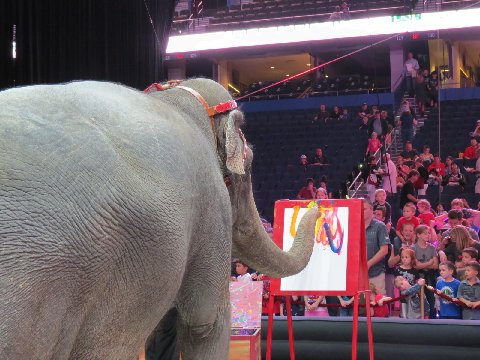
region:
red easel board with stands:
[275, 196, 373, 275]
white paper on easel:
[289, 209, 356, 289]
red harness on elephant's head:
[158, 74, 246, 128]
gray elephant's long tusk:
[216, 146, 345, 292]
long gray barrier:
[332, 311, 464, 355]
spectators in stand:
[322, 160, 477, 317]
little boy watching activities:
[231, 261, 258, 282]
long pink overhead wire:
[257, 39, 390, 104]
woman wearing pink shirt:
[359, 129, 408, 163]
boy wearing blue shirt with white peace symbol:
[423, 273, 464, 319]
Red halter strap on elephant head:
[211, 100, 239, 113]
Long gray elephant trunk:
[233, 209, 322, 280]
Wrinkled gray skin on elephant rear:
[5, 169, 156, 293]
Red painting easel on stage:
[264, 198, 369, 358]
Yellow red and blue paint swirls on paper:
[294, 201, 344, 255]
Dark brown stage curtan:
[25, 1, 168, 86]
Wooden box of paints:
[231, 277, 263, 358]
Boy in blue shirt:
[435, 264, 456, 319]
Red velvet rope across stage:
[285, 286, 473, 308]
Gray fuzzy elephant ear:
[220, 106, 250, 175]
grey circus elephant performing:
[68, 35, 417, 331]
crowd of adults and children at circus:
[222, 126, 462, 304]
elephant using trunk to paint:
[260, 177, 381, 336]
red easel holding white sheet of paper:
[264, 177, 375, 346]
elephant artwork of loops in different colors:
[278, 183, 354, 307]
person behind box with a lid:
[220, 249, 261, 349]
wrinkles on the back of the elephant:
[19, 138, 203, 276]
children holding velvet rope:
[374, 251, 467, 306]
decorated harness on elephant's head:
[145, 72, 245, 159]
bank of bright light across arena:
[164, 8, 458, 67]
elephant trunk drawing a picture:
[255, 181, 386, 318]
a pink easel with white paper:
[252, 185, 382, 359]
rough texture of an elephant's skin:
[12, 138, 156, 268]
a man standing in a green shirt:
[348, 189, 391, 303]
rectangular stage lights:
[151, 3, 478, 68]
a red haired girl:
[392, 241, 424, 282]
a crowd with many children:
[342, 119, 479, 320]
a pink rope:
[233, 27, 409, 105]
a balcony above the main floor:
[226, 36, 400, 137]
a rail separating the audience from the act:
[260, 307, 477, 359]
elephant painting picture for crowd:
[18, 19, 445, 333]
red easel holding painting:
[268, 184, 385, 349]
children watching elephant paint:
[352, 150, 472, 324]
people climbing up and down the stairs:
[350, 49, 430, 223]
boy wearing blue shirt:
[433, 252, 459, 324]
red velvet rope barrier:
[280, 278, 476, 314]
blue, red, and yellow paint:
[284, 195, 349, 258]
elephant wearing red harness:
[144, 53, 270, 227]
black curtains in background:
[9, 1, 166, 88]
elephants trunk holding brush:
[250, 182, 336, 282]